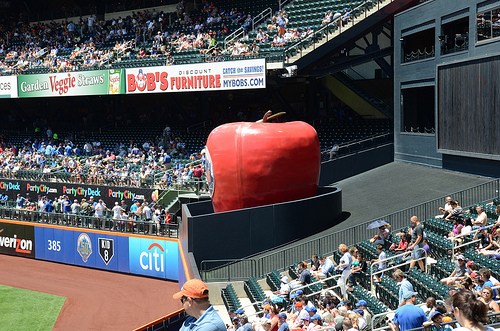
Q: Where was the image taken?
A: It was taken at the stadium.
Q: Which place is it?
A: It is a stadium.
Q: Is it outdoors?
A: Yes, it is outdoors.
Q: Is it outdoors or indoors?
A: It is outdoors.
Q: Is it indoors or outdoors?
A: It is outdoors.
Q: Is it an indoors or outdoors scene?
A: It is outdoors.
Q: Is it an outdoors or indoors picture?
A: It is outdoors.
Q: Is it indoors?
A: No, it is outdoors.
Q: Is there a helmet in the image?
A: No, there are no helmets.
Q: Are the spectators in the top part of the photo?
A: No, the spectators are in the bottom of the image.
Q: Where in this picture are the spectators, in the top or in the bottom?
A: The spectators are in the bottom of the image.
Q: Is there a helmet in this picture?
A: No, there are no helmets.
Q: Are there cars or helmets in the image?
A: No, there are no helmets or cars.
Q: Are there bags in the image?
A: Yes, there is a bag.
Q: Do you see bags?
A: Yes, there is a bag.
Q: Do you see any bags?
A: Yes, there is a bag.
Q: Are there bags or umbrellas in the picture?
A: Yes, there is a bag.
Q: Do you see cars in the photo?
A: No, there are no cars.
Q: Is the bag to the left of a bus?
A: No, the bag is to the left of a person.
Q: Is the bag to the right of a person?
A: No, the bag is to the left of a person.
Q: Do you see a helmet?
A: No, there are no helmets.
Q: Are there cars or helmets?
A: No, there are no cars or helmets.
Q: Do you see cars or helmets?
A: No, there are no cars or helmets.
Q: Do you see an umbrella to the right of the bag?
A: No, there is a person to the right of the bag.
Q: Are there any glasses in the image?
A: No, there are no glasses.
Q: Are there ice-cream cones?
A: No, there are no ice-cream cones.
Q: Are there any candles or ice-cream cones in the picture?
A: No, there are no ice-cream cones or candles.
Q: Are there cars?
A: No, there are no cars.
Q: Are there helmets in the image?
A: No, there are no helmets.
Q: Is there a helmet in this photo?
A: No, there are no helmets.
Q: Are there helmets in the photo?
A: No, there are no helmets.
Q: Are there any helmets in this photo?
A: No, there are no helmets.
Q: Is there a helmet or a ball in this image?
A: No, there are no helmets or balls.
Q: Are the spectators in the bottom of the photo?
A: Yes, the spectators are in the bottom of the image.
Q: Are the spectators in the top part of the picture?
A: No, the spectators are in the bottom of the image.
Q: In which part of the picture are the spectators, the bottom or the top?
A: The spectators are in the bottom of the image.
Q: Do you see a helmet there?
A: No, there are no helmets.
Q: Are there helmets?
A: No, there are no helmets.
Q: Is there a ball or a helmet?
A: No, there are no helmets or balls.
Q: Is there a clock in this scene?
A: No, there are no clocks.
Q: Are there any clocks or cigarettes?
A: No, there are no clocks or cigarettes.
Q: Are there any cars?
A: No, there are no cars.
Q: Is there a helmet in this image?
A: No, there are no helmets.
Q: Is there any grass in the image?
A: Yes, there is grass.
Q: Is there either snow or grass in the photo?
A: Yes, there is grass.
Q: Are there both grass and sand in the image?
A: No, there is grass but no sand.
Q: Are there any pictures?
A: No, there are no pictures.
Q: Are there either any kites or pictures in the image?
A: No, there are no pictures or kites.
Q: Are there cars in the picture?
A: No, there are no cars.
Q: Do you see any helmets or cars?
A: No, there are no cars or helmets.